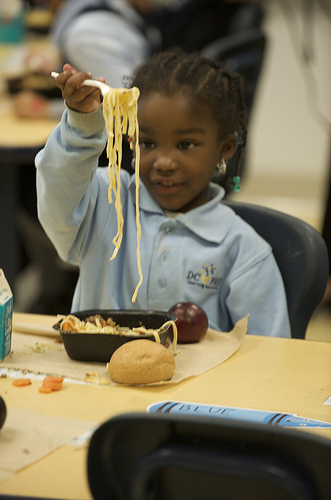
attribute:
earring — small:
[214, 157, 227, 176]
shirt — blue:
[31, 97, 294, 333]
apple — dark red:
[165, 298, 209, 341]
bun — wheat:
[105, 337, 178, 387]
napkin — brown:
[1, 311, 252, 388]